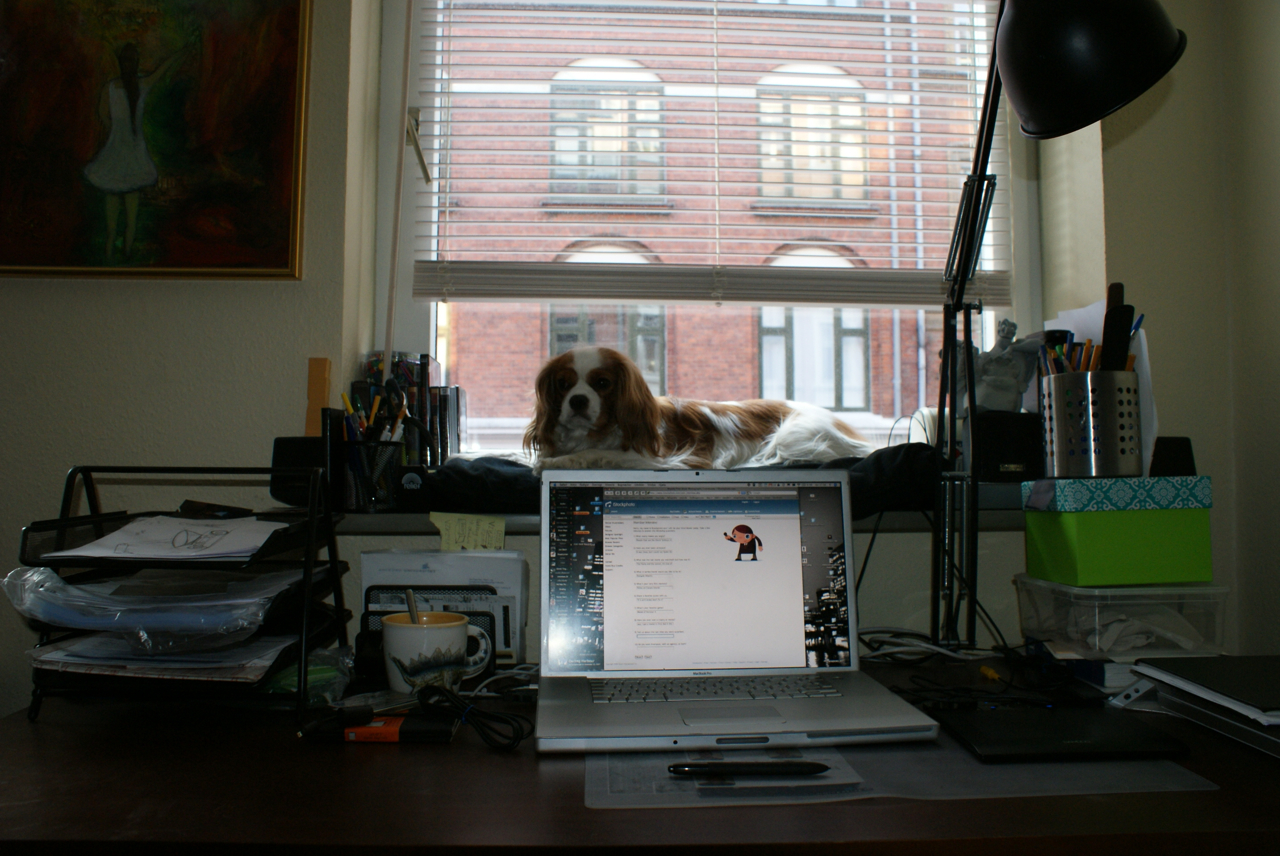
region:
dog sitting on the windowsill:
[528, 346, 862, 464]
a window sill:
[380, 448, 1153, 521]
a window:
[387, 8, 1030, 461]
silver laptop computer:
[532, 474, 934, 751]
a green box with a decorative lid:
[1022, 474, 1224, 585]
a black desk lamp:
[934, 8, 1191, 680]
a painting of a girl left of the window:
[0, 8, 312, 282]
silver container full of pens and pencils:
[1038, 284, 1151, 479]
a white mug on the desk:
[387, 595, 491, 686]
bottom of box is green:
[1030, 505, 1242, 583]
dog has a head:
[529, 340, 660, 449]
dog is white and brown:
[540, 344, 887, 470]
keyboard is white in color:
[551, 673, 891, 751]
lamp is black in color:
[987, 5, 1204, 154]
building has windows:
[442, 18, 917, 237]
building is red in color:
[458, 38, 547, 367]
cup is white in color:
[381, 607, 476, 692]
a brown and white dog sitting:
[528, 335, 860, 475]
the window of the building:
[543, 49, 676, 215]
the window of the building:
[753, 57, 879, 219]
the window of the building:
[543, 232, 680, 402]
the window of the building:
[751, 232, 880, 427]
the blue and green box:
[1013, 464, 1221, 582]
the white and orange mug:
[382, 602, 495, 678]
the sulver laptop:
[517, 457, 941, 753]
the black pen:
[663, 751, 840, 778]